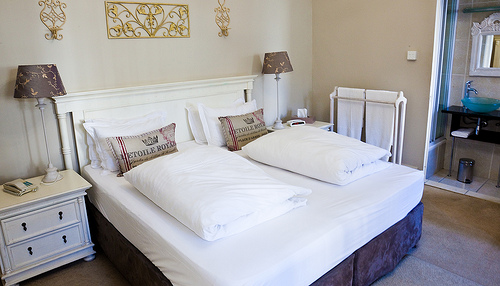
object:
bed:
[51, 72, 428, 286]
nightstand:
[0, 169, 98, 286]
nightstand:
[267, 120, 335, 134]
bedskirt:
[250, 172, 423, 286]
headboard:
[49, 74, 257, 169]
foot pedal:
[465, 179, 471, 184]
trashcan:
[457, 158, 476, 185]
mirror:
[476, 33, 500, 69]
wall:
[443, 4, 500, 183]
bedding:
[123, 147, 309, 242]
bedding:
[240, 126, 390, 187]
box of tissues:
[291, 115, 316, 124]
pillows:
[195, 98, 259, 147]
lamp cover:
[13, 63, 68, 99]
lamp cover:
[262, 50, 294, 74]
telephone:
[2, 178, 39, 197]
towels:
[365, 89, 398, 161]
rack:
[329, 86, 408, 163]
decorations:
[213, 1, 231, 38]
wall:
[1, 0, 438, 185]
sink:
[460, 96, 500, 112]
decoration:
[37, 0, 67, 41]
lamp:
[12, 64, 67, 184]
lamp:
[261, 50, 294, 130]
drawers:
[2, 198, 81, 246]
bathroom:
[0, 0, 499, 286]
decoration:
[106, 1, 190, 39]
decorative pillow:
[105, 123, 178, 177]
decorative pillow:
[216, 108, 270, 152]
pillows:
[81, 111, 171, 175]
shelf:
[441, 102, 500, 146]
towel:
[450, 128, 474, 138]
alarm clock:
[286, 119, 306, 127]